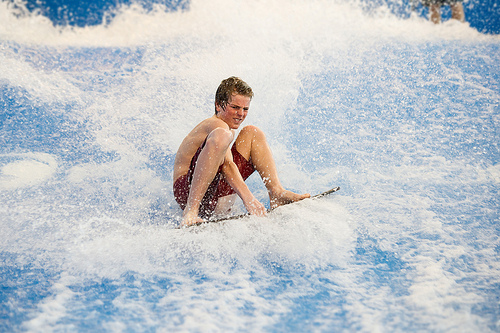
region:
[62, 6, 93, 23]
this is the water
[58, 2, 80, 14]
the water is blue in color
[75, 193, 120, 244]
this is raised water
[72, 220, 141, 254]
the water is white in color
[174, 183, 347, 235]
this is a surfboard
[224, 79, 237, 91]
this is some hair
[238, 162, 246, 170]
the short is red in color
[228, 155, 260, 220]
this is an arm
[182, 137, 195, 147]
this is the back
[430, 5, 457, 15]
these are two feet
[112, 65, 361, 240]
YOUNG BOY SKIM BOARDING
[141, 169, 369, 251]
SKIM BOARD UNDER BOY'S FEET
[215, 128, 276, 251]
BOY'S RIGHT ARM HOLDING BOARD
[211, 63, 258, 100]
WET BLONDE HAIR OF BOY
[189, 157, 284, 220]
RED BATHING SUIT ON BOY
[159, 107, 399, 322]
WHITE ROUGH SEA WATER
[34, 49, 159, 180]
WATER BEING SPLASHED INTO THE AIR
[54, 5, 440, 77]
CREST OF WAVE BEHIND BOY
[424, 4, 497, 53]
BROWN OBJECT OFF TO THE RIGHT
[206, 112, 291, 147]
KNEES OF SKIM BOARDER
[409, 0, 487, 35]
surfer's legs in the foamy wave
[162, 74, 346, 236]
surfer sitting on board and holding on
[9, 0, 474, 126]
very large wave in the ocean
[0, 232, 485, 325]
blue water with white foam from waves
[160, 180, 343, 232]
black board of a surfer in the ocean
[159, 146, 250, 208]
red shorts of a surfer in the ocean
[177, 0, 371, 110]
white foamy spray behind surfer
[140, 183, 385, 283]
surf board making a wave in the ocean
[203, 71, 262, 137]
surfer's head with dark brown hair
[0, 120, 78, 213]
foamy swirl in the ocean waves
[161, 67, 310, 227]
surfer on the water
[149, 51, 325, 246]
surfer wears red shorts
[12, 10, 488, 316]
big splashes in the water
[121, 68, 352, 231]
boy on a surfboard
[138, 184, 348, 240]
surfboard is small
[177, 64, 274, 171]
boy is blonde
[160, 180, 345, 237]
hand holding a surfboard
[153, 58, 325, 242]
boy is crouched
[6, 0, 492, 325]
blue water is foamy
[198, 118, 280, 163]
knees of boy are bend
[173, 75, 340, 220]
A boy surfing.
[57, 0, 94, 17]
Part of the clear blue water.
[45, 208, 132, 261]
Part of the foamy waves.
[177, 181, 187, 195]
Part of the boy's red swimsuit.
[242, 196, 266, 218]
The boy's hand.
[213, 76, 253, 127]
The boy's head.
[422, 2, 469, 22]
The legs of a person in the background.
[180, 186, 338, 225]
The top of the surfboard.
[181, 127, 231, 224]
The boy's leg.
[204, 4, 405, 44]
A large white wave.